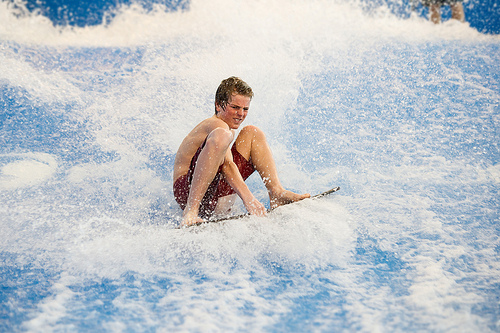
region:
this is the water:
[62, 6, 93, 23]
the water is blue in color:
[58, 2, 80, 14]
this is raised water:
[75, 193, 120, 244]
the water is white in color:
[72, 220, 141, 254]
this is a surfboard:
[174, 183, 347, 235]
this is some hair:
[224, 79, 237, 91]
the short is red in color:
[238, 162, 246, 170]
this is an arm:
[228, 155, 260, 220]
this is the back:
[182, 137, 195, 147]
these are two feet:
[430, 5, 457, 15]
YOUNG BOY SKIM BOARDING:
[112, 65, 361, 240]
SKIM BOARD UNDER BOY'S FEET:
[141, 169, 369, 251]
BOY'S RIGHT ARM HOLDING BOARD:
[215, 128, 276, 251]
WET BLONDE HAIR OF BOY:
[211, 63, 258, 100]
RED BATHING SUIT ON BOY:
[189, 157, 284, 220]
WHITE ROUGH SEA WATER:
[159, 107, 399, 322]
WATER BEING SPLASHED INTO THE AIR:
[34, 49, 159, 180]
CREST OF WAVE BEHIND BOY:
[54, 5, 440, 77]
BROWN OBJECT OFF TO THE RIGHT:
[424, 4, 497, 53]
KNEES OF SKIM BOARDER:
[206, 112, 291, 147]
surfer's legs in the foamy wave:
[409, 0, 487, 35]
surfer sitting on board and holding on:
[162, 74, 346, 236]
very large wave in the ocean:
[9, 0, 474, 126]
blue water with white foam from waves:
[0, 232, 485, 325]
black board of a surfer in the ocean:
[160, 180, 343, 232]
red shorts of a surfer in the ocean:
[159, 146, 250, 208]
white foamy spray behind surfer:
[177, 0, 371, 110]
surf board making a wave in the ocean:
[140, 183, 385, 283]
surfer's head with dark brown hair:
[203, 71, 262, 137]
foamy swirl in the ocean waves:
[0, 120, 78, 213]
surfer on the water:
[161, 67, 310, 227]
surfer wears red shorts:
[149, 51, 325, 246]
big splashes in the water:
[12, 10, 488, 316]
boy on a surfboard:
[121, 68, 352, 231]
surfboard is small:
[138, 184, 348, 240]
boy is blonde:
[177, 64, 274, 171]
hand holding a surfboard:
[160, 180, 345, 237]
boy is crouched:
[153, 58, 325, 242]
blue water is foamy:
[6, 0, 492, 325]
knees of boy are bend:
[198, 118, 280, 163]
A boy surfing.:
[173, 75, 340, 220]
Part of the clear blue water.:
[57, 0, 94, 17]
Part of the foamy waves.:
[45, 208, 132, 261]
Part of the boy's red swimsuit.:
[177, 181, 187, 195]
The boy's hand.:
[242, 196, 266, 218]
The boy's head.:
[213, 76, 253, 127]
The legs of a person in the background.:
[422, 2, 469, 22]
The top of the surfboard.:
[180, 186, 338, 225]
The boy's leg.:
[181, 127, 231, 224]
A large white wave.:
[204, 4, 405, 44]